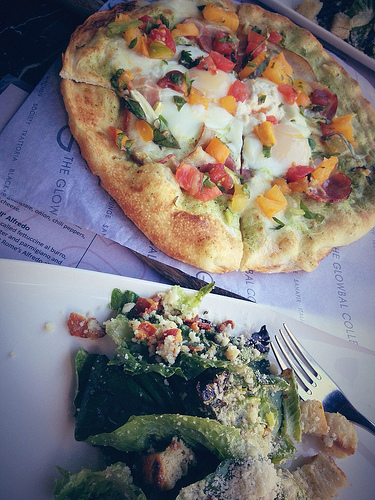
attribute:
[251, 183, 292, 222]
pepper — yellow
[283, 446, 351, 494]
croutons — three, crispy, cheese-coated, cheese-covered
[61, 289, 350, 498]
salad — green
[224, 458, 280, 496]
cheese — parmesan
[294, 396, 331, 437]
crouton — garlic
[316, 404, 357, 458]
crouton — garlic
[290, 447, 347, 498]
crouton — garlic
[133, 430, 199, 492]
crouton — garlic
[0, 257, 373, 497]
plate — white, large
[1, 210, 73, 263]
restaurant menu — partial restaurant menu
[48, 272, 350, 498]
salad — green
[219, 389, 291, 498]
parmesan — sprinkled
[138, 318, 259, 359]
parmesan — sprinkled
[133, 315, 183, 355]
cheese — white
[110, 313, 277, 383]
leaf — green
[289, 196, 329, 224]
scallions — green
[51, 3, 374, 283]
pizza — sliced, thin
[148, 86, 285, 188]
cheese — spread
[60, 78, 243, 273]
crust — dry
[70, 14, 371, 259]
pizza — vegetarian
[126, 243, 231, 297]
plate — straw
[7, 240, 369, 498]
table — white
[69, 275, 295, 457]
salad — green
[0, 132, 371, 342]
tissue liner — food grade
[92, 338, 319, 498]
salad — green 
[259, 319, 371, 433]
fork — Metallic 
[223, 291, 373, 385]
plate — green 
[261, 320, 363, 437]
fork — stainless, steel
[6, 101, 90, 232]
paper — wrapping paper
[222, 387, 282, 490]
cheese — grated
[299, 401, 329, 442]
crouton — cheese-coated, crispy, cheese-covered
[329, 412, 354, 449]
crouton — cheese-covered , crispy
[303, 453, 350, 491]
crouton — crispy